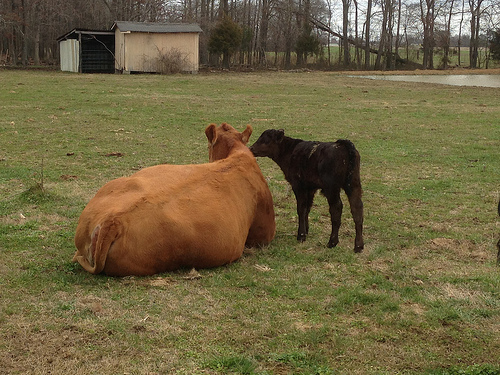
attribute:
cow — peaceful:
[81, 124, 273, 266]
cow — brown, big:
[70, 124, 274, 280]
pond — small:
[386, 57, 496, 107]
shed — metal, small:
[68, 19, 118, 73]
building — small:
[118, 30, 199, 74]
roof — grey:
[113, 17, 204, 36]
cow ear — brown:
[241, 126, 256, 144]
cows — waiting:
[58, 127, 377, 285]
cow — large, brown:
[64, 112, 380, 259]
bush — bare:
[152, 52, 204, 82]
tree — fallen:
[291, 13, 405, 59]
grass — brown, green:
[2, 67, 484, 373]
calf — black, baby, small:
[251, 128, 367, 253]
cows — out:
[62, 106, 376, 296]